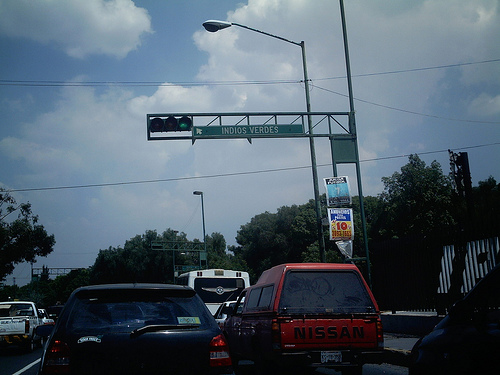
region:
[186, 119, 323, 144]
"Indios Verdes"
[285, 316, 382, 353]
"Nissan" on the car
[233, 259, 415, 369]
A red car in motion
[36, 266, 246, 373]
Black car in motion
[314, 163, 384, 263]
Signs on the pole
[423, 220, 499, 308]
White letters to the side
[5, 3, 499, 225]
Clouds in the sky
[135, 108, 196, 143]
The light is green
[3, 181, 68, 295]
Trees in the corner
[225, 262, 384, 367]
red Nissan truck with canopy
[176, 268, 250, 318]
small white bus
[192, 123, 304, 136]
long green sign with white lettering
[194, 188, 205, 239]
tall street light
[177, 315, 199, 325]
sticker in back window of the black car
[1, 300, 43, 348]
white pick up with yellow and black bumper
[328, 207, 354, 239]
yellow and blue advertisement that says 10 in red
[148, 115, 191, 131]
street light with green light lit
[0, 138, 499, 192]
power line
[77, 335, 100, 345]
white bumper sticker on the black car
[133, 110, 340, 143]
green and white highway sign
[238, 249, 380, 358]
red car on highway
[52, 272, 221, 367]
black car on highway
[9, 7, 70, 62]
white clouds in blue sky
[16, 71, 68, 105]
white clouds in blue sky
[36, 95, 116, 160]
white clouds in blue sky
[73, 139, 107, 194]
white clouds in blue sky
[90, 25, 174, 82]
white clouds in blue sky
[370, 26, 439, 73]
white clouds in blue sky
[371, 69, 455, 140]
white clouds in blue sky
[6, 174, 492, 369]
the highway is congested with traffic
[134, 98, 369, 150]
traffic signal light is green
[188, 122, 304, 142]
a directional sign is above the traffic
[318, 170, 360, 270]
advertisement signs are on the side of the road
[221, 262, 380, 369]
a red cab is on the pickup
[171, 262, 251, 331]
a white small bus is in front of the pickup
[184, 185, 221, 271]
a light is on top of the pole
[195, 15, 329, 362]
a lamp is on a stainless steel pole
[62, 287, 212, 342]
a wiper is on the back window of the car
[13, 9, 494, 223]
the sky is blue with scattered clouds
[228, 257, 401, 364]
the van is red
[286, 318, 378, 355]
the model is nissan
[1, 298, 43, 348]
the pickup is white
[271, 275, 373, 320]
the window has dust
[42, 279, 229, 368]
the car is blue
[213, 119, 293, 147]
indios verdes is on the sign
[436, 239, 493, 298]
the pole is white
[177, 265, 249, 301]
the van is white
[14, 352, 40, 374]
the line is white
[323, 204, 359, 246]
poster is on the pole